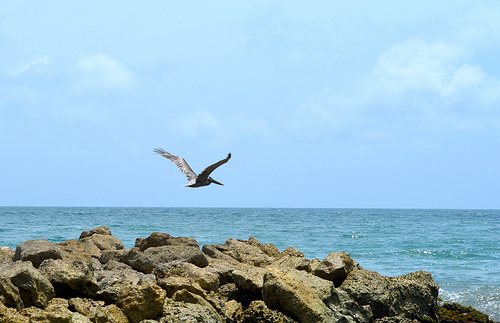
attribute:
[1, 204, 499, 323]
ocean — calm, green blue, wet, water, blue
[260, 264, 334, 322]
rocks — jagged, light brown, dry, brown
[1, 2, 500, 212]
sky — blue, cloudy, beautiful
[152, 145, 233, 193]
pelican — flying, black, grey, alone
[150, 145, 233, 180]
wingspan — wide, large, long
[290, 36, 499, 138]
clouds — light